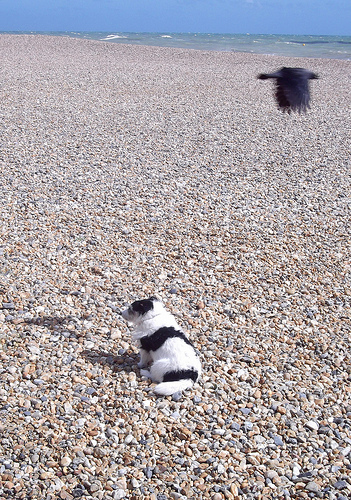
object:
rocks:
[0, 34, 95, 213]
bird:
[257, 64, 323, 117]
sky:
[1, 0, 349, 33]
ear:
[134, 297, 154, 314]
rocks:
[58, 111, 92, 139]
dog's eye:
[127, 308, 134, 315]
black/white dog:
[120, 294, 202, 396]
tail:
[148, 375, 200, 400]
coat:
[144, 314, 197, 381]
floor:
[61, 434, 299, 477]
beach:
[0, 30, 349, 498]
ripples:
[99, 27, 175, 45]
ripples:
[271, 36, 349, 54]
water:
[77, 32, 341, 62]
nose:
[119, 311, 123, 317]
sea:
[57, 11, 326, 64]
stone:
[180, 238, 299, 321]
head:
[120, 294, 164, 322]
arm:
[139, 349, 149, 366]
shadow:
[20, 312, 89, 340]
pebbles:
[7, 445, 33, 491]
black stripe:
[140, 323, 194, 352]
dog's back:
[147, 322, 198, 364]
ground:
[0, 34, 349, 498]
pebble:
[273, 437, 283, 444]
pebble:
[153, 465, 162, 473]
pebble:
[305, 481, 321, 491]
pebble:
[305, 420, 319, 431]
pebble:
[121, 432, 135, 444]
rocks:
[212, 405, 218, 412]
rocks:
[268, 432, 282, 445]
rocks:
[240, 350, 252, 363]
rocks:
[23, 362, 31, 377]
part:
[49, 398, 99, 441]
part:
[304, 421, 312, 428]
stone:
[307, 344, 350, 431]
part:
[210, 411, 253, 475]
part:
[289, 414, 333, 471]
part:
[253, 291, 321, 371]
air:
[274, 5, 304, 35]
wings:
[255, 68, 283, 91]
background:
[171, 7, 338, 56]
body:
[82, 25, 337, 55]